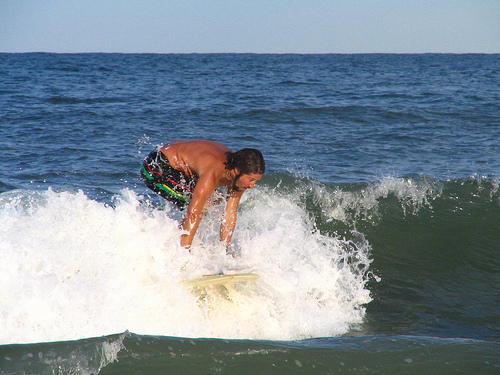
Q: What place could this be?
A: It is an ocean.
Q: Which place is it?
A: It is an ocean.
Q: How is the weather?
A: It is clear.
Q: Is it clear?
A: Yes, it is clear.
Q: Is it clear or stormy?
A: It is clear.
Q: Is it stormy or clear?
A: It is clear.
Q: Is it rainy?
A: No, it is clear.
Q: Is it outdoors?
A: Yes, it is outdoors.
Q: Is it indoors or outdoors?
A: It is outdoors.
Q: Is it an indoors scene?
A: No, it is outdoors.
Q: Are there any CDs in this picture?
A: No, there are no cds.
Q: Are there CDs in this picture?
A: No, there are no cds.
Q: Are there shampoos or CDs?
A: No, there are no CDs or shampoos.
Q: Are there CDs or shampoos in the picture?
A: No, there are no CDs or shampoos.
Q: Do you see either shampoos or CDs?
A: No, there are no CDs or shampoos.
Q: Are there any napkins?
A: No, there are no napkins.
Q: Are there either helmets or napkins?
A: No, there are no napkins or helmets.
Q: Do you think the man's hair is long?
A: Yes, the hair is long.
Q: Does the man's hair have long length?
A: Yes, the hair is long.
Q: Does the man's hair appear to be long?
A: Yes, the hair is long.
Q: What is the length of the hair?
A: The hair is long.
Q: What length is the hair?
A: The hair is long.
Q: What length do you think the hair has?
A: The hair has long length.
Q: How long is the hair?
A: The hair is long.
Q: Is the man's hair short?
A: No, the hair is long.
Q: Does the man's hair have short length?
A: No, the hair is long.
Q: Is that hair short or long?
A: The hair is long.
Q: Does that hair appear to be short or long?
A: The hair is long.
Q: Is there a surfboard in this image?
A: Yes, there is a surfboard.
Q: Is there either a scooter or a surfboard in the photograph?
A: Yes, there is a surfboard.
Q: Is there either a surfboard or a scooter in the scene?
A: Yes, there is a surfboard.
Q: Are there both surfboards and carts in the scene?
A: No, there is a surfboard but no carts.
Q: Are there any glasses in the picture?
A: No, there are no glasses.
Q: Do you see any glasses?
A: No, there are no glasses.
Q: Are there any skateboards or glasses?
A: No, there are no glasses or skateboards.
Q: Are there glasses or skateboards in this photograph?
A: No, there are no glasses or skateboards.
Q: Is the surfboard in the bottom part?
A: Yes, the surfboard is in the bottom of the image.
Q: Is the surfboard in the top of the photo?
A: No, the surfboard is in the bottom of the image.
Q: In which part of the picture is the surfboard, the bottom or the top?
A: The surfboard is in the bottom of the image.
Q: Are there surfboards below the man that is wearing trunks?
A: Yes, there is a surfboard below the man.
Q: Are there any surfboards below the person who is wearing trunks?
A: Yes, there is a surfboard below the man.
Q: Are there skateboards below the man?
A: No, there is a surfboard below the man.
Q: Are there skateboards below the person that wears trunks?
A: No, there is a surfboard below the man.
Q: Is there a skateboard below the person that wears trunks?
A: No, there is a surfboard below the man.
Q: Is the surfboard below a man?
A: Yes, the surfboard is below a man.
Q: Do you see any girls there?
A: No, there are no girls.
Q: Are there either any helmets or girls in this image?
A: No, there are no girls or helmets.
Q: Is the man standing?
A: Yes, the man is standing.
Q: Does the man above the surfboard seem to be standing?
A: Yes, the man is standing.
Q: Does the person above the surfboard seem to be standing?
A: Yes, the man is standing.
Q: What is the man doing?
A: The man is standing.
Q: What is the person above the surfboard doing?
A: The man is standing.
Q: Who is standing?
A: The man is standing.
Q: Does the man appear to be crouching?
A: No, the man is standing.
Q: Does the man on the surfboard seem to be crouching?
A: No, the man is standing.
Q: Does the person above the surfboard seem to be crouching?
A: No, the man is standing.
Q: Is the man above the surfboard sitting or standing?
A: The man is standing.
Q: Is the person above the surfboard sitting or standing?
A: The man is standing.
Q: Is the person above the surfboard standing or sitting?
A: The man is standing.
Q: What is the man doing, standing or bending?
A: The man is standing.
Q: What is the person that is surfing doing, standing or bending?
A: The man is standing.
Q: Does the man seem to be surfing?
A: Yes, the man is surfing.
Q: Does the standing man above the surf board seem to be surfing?
A: Yes, the man is surfing.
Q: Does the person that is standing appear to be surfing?
A: Yes, the man is surfing.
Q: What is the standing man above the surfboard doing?
A: The man is surfing.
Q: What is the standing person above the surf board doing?
A: The man is surfing.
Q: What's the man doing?
A: The man is surfing.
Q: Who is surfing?
A: The man is surfing.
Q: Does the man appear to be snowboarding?
A: No, the man is surfing.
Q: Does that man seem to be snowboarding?
A: No, the man is surfing.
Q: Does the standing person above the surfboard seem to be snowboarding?
A: No, the man is surfing.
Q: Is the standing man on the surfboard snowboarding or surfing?
A: The man is surfing.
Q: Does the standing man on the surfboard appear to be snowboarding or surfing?
A: The man is surfing.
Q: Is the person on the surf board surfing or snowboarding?
A: The man is surfing.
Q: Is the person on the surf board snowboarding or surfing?
A: The man is surfing.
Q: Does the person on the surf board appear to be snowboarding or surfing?
A: The man is surfing.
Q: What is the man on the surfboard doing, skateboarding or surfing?
A: The man is surfing.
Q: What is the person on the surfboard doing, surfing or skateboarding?
A: The man is surfing.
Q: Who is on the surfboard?
A: The man is on the surfboard.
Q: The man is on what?
A: The man is on the surfboard.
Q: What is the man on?
A: The man is on the surfboard.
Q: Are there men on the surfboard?
A: Yes, there is a man on the surfboard.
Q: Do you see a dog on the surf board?
A: No, there is a man on the surf board.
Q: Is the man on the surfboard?
A: Yes, the man is on the surfboard.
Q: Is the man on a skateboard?
A: No, the man is on the surfboard.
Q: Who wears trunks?
A: The man wears trunks.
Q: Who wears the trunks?
A: The man wears trunks.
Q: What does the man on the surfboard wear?
A: The man wears trunks.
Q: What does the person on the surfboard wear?
A: The man wears trunks.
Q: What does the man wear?
A: The man wears trunks.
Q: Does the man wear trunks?
A: Yes, the man wears trunks.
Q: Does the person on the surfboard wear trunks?
A: Yes, the man wears trunks.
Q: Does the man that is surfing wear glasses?
A: No, the man wears trunks.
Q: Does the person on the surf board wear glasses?
A: No, the man wears trunks.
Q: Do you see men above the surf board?
A: Yes, there is a man above the surf board.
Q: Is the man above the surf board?
A: Yes, the man is above the surf board.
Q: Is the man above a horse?
A: No, the man is above the surf board.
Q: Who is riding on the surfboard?
A: The man is riding on the surfboard.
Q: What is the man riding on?
A: The man is riding on the surfboard.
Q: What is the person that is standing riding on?
A: The man is riding on the surfboard.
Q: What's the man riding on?
A: The man is riding on the surfboard.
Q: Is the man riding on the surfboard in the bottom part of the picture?
A: Yes, the man is riding on the surfboard.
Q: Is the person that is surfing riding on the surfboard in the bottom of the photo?
A: Yes, the man is riding on the surfboard.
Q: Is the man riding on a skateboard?
A: No, the man is riding on the surfboard.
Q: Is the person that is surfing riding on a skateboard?
A: No, the man is riding on the surfboard.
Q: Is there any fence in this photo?
A: No, there are no fences.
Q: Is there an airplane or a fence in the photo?
A: No, there are no fences or airplanes.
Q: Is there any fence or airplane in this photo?
A: No, there are no fences or airplanes.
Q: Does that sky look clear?
A: Yes, the sky is clear.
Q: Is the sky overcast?
A: No, the sky is clear.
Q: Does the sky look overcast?
A: No, the sky is clear.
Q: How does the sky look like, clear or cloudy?
A: The sky is clear.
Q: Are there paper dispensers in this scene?
A: No, there are no paper dispensers.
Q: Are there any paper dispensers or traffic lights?
A: No, there are no paper dispensers or traffic lights.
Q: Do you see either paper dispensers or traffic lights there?
A: No, there are no paper dispensers or traffic lights.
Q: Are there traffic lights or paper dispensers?
A: No, there are no paper dispensers or traffic lights.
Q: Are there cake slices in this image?
A: No, there are no cake slices.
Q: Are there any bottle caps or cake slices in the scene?
A: No, there are no cake slices or bottle caps.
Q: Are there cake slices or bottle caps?
A: No, there are no cake slices or bottle caps.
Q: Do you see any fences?
A: No, there are no fences.